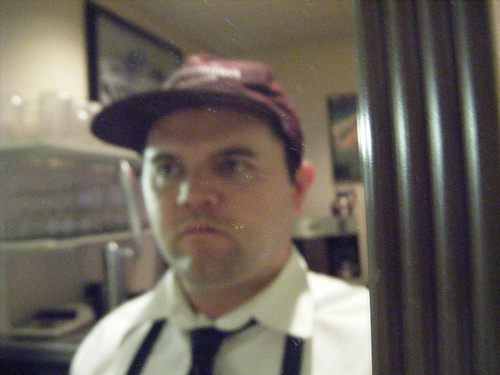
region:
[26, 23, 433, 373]
a restaurant worker wearing a hat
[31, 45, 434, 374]
a bus boy in a restaurant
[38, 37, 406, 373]
a restaurant worker with a tie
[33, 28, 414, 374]
a restaurant worker wearing a tie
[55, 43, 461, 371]
a restaurant worker wearing a tie and a hat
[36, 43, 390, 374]
a man with a white shirt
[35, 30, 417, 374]
man with a white shirt and black tie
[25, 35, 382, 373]
man with a white shirt, black tie and red hat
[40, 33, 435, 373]
man wearing a tie and apron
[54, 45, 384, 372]
a restaurant worker in uniform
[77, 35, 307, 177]
man is wearing a cap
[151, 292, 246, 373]
man is wearing a tie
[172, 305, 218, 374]
man is wearing a tie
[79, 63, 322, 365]
this is a man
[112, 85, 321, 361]
the man is staring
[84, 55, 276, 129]
this is the cap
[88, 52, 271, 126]
the cap is red in color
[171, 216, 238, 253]
this is the mouth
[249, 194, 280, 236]
the man is light skinned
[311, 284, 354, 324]
this is the t shirt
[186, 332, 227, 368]
this is a neck tie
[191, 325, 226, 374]
the tie is black in color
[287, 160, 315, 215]
this is the ear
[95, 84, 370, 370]
this is a man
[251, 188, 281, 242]
the man is light skinned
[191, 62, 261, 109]
this is a cap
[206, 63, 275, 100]
the cap is red in color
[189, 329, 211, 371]
this is a neck tie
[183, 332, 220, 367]
the tie is black in color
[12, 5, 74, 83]
this is the wall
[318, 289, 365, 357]
this is a shirt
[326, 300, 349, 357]
the shirt is white in color